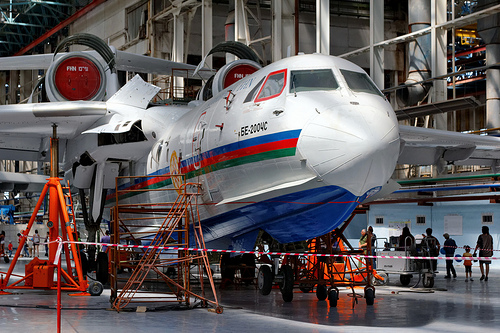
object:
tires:
[327, 291, 339, 308]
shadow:
[325, 307, 427, 324]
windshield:
[294, 72, 330, 87]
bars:
[226, 126, 239, 146]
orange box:
[319, 261, 347, 285]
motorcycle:
[400, 119, 491, 169]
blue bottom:
[125, 184, 383, 259]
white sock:
[465, 266, 474, 278]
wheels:
[364, 288, 375, 306]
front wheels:
[254, 264, 297, 297]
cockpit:
[252, 68, 384, 104]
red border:
[252, 67, 287, 103]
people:
[440, 232, 459, 281]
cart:
[370, 235, 437, 288]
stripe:
[103, 127, 304, 205]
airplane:
[0, 32, 499, 296]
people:
[396, 225, 442, 273]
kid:
[461, 245, 475, 283]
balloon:
[454, 254, 462, 263]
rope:
[22, 235, 499, 266]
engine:
[44, 50, 107, 102]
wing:
[397, 124, 499, 165]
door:
[190, 106, 215, 207]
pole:
[54, 236, 64, 333]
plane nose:
[296, 103, 401, 197]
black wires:
[0, 301, 212, 312]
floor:
[286, 308, 388, 323]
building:
[0, 0, 500, 270]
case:
[107, 173, 225, 315]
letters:
[240, 125, 249, 136]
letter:
[249, 121, 268, 135]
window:
[254, 71, 287, 100]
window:
[288, 68, 341, 94]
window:
[337, 68, 389, 101]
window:
[242, 72, 267, 105]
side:
[109, 117, 283, 204]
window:
[239, 72, 299, 111]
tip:
[31, 263, 55, 289]